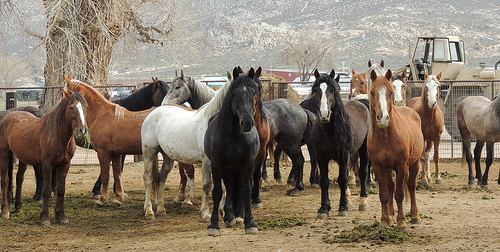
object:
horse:
[366, 69, 424, 233]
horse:
[407, 71, 444, 184]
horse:
[392, 71, 407, 106]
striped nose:
[379, 86, 388, 117]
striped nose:
[426, 78, 439, 103]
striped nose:
[392, 79, 405, 100]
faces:
[314, 80, 333, 121]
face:
[370, 83, 393, 126]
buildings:
[199, 65, 352, 99]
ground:
[3, 159, 498, 249]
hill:
[184, 7, 455, 54]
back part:
[151, 108, 172, 142]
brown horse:
[1, 88, 89, 226]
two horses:
[310, 68, 424, 232]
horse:
[309, 69, 371, 219]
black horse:
[203, 67, 261, 236]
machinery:
[394, 36, 499, 139]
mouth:
[74, 129, 88, 138]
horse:
[139, 71, 233, 223]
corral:
[2, 62, 500, 252]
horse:
[160, 69, 316, 197]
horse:
[111, 77, 170, 112]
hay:
[64, 189, 93, 212]